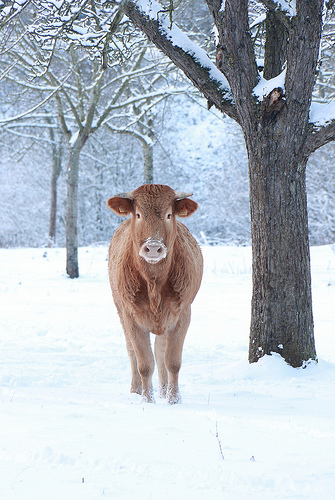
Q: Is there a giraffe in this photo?
A: No, there are no giraffes.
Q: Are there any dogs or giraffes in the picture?
A: No, there are no giraffes or dogs.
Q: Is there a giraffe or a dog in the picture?
A: No, there are no giraffes or dogs.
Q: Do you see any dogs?
A: No, there are no dogs.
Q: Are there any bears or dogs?
A: No, there are no dogs or bears.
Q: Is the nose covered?
A: Yes, the nose is covered.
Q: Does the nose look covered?
A: Yes, the nose is covered.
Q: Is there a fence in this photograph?
A: No, there are no fences.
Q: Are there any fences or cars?
A: No, there are no fences or cars.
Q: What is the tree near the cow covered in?
A: The tree is covered in snow.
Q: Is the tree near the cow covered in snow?
A: Yes, the tree is covered in snow.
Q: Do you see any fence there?
A: No, there are no fences.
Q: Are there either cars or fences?
A: No, there are no fences or cars.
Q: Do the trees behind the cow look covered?
A: No, the trees are bare.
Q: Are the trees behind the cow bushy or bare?
A: The trees are bare.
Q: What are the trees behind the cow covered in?
A: The trees are covered in snow.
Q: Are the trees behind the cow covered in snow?
A: Yes, the trees are covered in snow.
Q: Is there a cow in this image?
A: Yes, there is a cow.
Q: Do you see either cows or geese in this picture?
A: Yes, there is a cow.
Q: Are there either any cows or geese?
A: Yes, there is a cow.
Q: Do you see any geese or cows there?
A: Yes, there is a cow.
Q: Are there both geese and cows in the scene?
A: No, there is a cow but no geese.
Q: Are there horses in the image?
A: No, there are no horses.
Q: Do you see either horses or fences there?
A: No, there are no horses or fences.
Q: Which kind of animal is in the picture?
A: The animal is a cow.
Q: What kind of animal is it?
A: The animal is a cow.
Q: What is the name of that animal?
A: This is a cow.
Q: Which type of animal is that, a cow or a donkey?
A: This is a cow.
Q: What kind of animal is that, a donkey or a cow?
A: This is a cow.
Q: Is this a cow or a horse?
A: This is a cow.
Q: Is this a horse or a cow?
A: This is a cow.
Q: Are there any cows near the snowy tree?
A: Yes, there is a cow near the tree.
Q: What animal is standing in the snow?
A: The cow is standing in the snow.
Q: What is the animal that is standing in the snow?
A: The animal is a cow.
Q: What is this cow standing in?
A: The cow is standing in the snow.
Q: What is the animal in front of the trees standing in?
A: The cow is standing in the snow.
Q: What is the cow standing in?
A: The cow is standing in the snow.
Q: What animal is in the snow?
A: The cow is in the snow.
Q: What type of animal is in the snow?
A: The animal is a cow.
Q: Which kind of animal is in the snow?
A: The animal is a cow.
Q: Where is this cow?
A: The cow is in the snow.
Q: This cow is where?
A: The cow is in the snow.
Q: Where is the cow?
A: The cow is in the snow.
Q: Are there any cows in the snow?
A: Yes, there is a cow in the snow.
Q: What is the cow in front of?
A: The cow is in front of the trees.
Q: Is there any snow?
A: Yes, there is snow.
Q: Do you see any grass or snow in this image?
A: Yes, there is snow.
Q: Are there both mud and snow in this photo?
A: No, there is snow but no mud.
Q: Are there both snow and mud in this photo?
A: No, there is snow but no mud.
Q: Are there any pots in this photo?
A: No, there are no pots.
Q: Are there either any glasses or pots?
A: No, there are no pots or glasses.